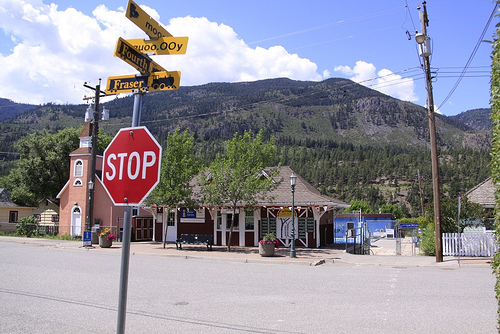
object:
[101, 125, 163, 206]
sign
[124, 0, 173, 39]
sign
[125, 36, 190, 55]
sign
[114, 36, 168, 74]
sign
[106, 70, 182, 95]
sign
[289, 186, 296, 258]
light post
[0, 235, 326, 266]
sidewalk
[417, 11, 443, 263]
utility pole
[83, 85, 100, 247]
utility pole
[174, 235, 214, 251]
bench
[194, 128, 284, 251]
trees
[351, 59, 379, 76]
clouds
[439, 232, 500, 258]
fence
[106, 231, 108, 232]
flowers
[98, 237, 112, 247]
planter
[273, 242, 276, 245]
flowers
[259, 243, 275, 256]
planter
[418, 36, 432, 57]
transformer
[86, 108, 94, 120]
transformer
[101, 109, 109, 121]
transformer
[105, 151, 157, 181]
lettering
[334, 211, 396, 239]
building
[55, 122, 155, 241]
church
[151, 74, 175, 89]
train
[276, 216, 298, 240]
sign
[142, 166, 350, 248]
building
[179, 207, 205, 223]
sign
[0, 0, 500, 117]
sky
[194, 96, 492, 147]
mountain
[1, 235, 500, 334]
street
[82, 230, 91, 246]
sign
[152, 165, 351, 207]
roof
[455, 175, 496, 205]
roof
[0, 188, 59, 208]
roof